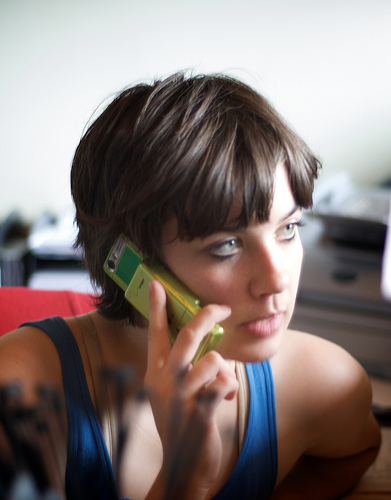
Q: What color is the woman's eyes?
A: Green.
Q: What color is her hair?
A: Dark brown.